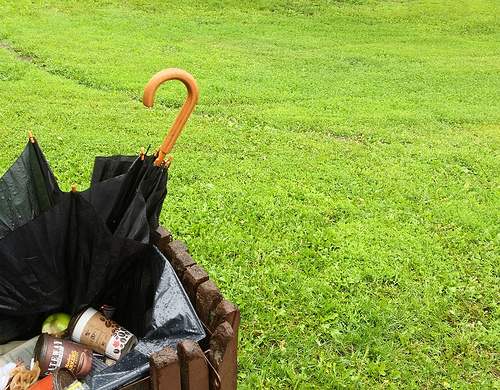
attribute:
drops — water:
[2, 154, 56, 228]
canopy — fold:
[6, 130, 176, 326]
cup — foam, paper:
[66, 300, 134, 363]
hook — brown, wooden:
[135, 63, 199, 156]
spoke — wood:
[23, 128, 36, 143]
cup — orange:
[22, 366, 76, 389]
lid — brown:
[50, 364, 77, 389]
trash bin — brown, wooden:
[109, 225, 241, 389]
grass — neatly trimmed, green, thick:
[0, 1, 499, 389]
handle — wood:
[141, 66, 201, 151]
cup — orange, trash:
[15, 344, 65, 387]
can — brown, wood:
[134, 231, 284, 379]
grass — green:
[277, 62, 453, 320]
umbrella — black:
[2, 56, 207, 341]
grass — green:
[299, 162, 457, 363]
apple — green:
[37, 309, 75, 334]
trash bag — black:
[150, 251, 210, 345]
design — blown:
[93, 309, 114, 332]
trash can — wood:
[6, 195, 251, 387]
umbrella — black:
[1, 134, 173, 330]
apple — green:
[35, 306, 76, 342]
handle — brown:
[135, 61, 202, 161]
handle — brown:
[135, 57, 204, 157]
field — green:
[0, 2, 494, 387]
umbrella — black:
[8, 64, 204, 330]